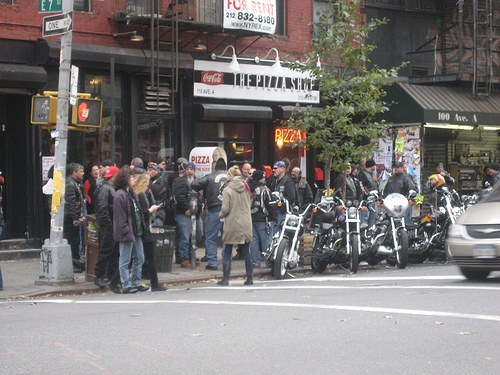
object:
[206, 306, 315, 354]
part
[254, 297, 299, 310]
part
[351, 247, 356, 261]
part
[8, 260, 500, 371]
road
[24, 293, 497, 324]
line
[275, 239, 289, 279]
wheel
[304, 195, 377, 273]
motorcycles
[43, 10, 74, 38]
one way sign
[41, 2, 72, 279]
post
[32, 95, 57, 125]
pedestrian crossing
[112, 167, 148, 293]
people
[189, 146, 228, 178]
pizza sign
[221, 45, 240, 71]
lights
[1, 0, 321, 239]
building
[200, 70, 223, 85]
coca cola logo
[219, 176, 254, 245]
jacket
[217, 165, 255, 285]
woman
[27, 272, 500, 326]
crosswalk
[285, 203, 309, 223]
windshield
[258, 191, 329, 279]
motorcycle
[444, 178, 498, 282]
car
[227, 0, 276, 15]
for rent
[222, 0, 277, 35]
sign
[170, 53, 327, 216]
pizza shop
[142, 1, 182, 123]
fire escape ladder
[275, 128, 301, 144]
pizza sign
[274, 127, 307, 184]
window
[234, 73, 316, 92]
pizza shop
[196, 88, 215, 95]
100 ave a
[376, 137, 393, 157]
informational papers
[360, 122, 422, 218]
board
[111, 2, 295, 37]
balcony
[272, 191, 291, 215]
handle bars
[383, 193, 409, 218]
helmet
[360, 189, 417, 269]
motorcycle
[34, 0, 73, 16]
street sign